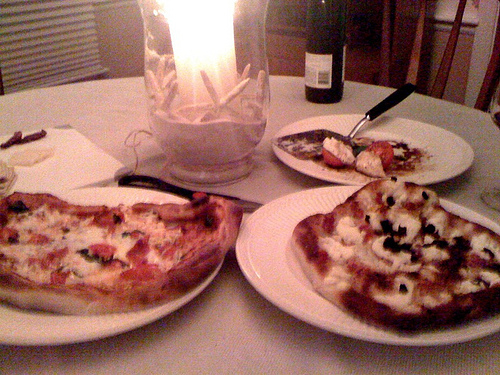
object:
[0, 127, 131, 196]
plate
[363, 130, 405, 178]
ground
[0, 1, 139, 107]
blinds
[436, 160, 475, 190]
ground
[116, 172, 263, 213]
scissors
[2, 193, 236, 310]
pizza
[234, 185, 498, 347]
plate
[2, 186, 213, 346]
plate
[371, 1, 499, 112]
chair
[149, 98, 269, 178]
sand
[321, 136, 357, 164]
shells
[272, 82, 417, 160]
spatula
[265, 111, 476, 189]
plate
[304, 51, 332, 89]
sticker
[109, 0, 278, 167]
starvish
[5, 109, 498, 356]
three plates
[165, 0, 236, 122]
candle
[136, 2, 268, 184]
jar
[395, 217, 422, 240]
feta cheese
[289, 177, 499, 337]
pizza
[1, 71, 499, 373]
cloth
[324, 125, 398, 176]
pastry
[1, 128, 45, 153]
appetizers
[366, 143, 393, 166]
tomato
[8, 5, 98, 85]
window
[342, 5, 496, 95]
back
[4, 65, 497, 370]
table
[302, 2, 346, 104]
bottle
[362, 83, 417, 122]
handle